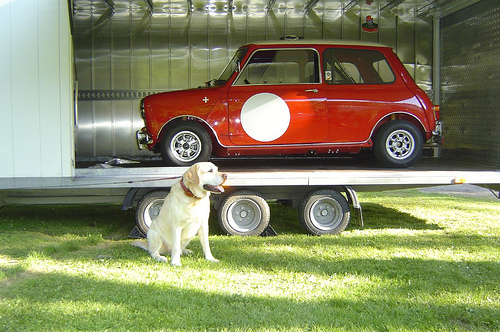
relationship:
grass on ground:
[0, 189, 500, 331] [2, 182, 498, 329]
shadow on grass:
[5, 202, 496, 330] [84, 270, 224, 312]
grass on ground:
[0, 189, 500, 331] [3, 201, 497, 331]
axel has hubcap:
[217, 188, 272, 237] [229, 200, 261, 232]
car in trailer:
[133, 29, 451, 168] [3, 5, 498, 230]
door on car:
[225, 43, 329, 143] [133, 29, 451, 168]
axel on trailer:
[301, 187, 350, 238] [22, 37, 489, 237]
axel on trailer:
[220, 185, 270, 236] [22, 37, 489, 237]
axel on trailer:
[134, 187, 170, 234] [22, 37, 489, 237]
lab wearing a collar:
[128, 152, 239, 272] [180, 178, 196, 197]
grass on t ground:
[0, 189, 500, 331] [242, 277, 298, 326]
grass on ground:
[398, 229, 485, 293] [8, 213, 485, 325]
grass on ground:
[0, 189, 500, 331] [8, 213, 485, 325]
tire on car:
[153, 120, 223, 166] [133, 29, 451, 168]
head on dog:
[179, 160, 229, 197] [129, 160, 227, 266]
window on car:
[319, 50, 395, 85] [133, 29, 451, 168]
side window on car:
[226, 48, 323, 88] [133, 29, 451, 168]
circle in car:
[237, 89, 293, 141] [133, 29, 451, 168]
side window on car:
[232, 48, 321, 86] [138, 40, 444, 163]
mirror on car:
[232, 61, 244, 74] [133, 29, 451, 168]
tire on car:
[379, 115, 423, 172] [122, 9, 442, 161]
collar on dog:
[180, 178, 196, 197] [129, 160, 227, 266]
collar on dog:
[178, 176, 204, 200] [133, 147, 256, 305]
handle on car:
[304, 87, 319, 94] [142, 64, 420, 155]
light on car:
[431, 101, 441, 121] [138, 40, 444, 163]